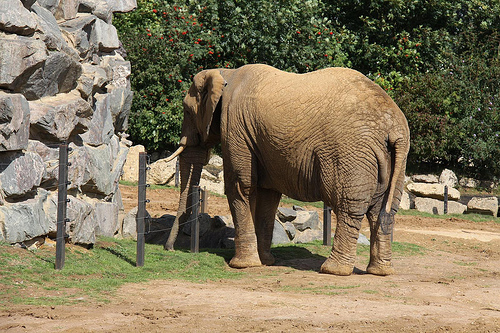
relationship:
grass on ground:
[5, 231, 218, 331] [13, 177, 500, 331]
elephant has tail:
[162, 64, 410, 276] [372, 139, 413, 269]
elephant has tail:
[162, 64, 410, 276] [377, 130, 409, 236]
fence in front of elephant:
[2, 140, 334, 283] [162, 64, 410, 276]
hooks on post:
[56, 143, 201, 266] [55, 145, 200, 265]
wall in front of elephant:
[1, 0, 137, 250] [164, 63, 410, 273]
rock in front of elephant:
[1, 2, 500, 248] [164, 63, 410, 273]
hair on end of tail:
[378, 210, 392, 233] [372, 139, 413, 269]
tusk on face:
[158, 144, 218, 188] [178, 66, 216, 162]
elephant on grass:
[162, 64, 410, 276] [1, 180, 499, 307]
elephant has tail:
[162, 64, 410, 276] [374, 126, 410, 236]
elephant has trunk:
[162, 64, 410, 276] [164, 124, 209, 249]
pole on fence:
[136, 152, 147, 264] [2, 140, 334, 283]